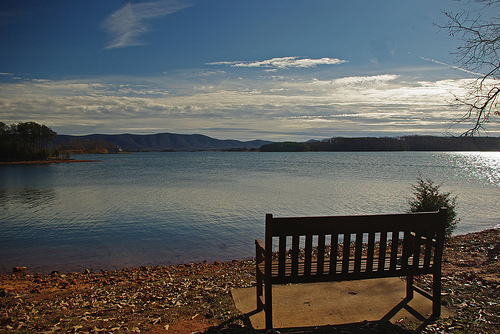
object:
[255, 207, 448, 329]
bench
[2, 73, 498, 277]
view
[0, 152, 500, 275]
water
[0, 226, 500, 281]
shore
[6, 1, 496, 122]
sky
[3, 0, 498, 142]
clouds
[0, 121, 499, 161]
mountains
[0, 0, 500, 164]
background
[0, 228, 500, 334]
leaves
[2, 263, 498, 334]
ground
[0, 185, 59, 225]
reflection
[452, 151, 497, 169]
reflection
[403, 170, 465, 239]
tree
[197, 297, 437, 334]
shadow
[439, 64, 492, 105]
sun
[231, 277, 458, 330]
cement pad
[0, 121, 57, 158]
trees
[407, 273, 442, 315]
legs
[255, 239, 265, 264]
armrest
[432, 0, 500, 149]
branches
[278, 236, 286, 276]
slat